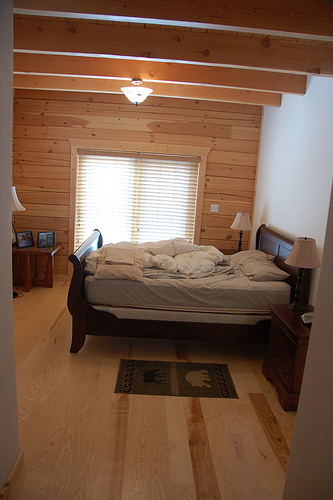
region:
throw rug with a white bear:
[117, 355, 244, 401]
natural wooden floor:
[144, 428, 233, 495]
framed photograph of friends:
[37, 229, 56, 247]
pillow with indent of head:
[241, 261, 288, 280]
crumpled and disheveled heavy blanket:
[102, 237, 223, 278]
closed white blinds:
[69, 142, 205, 250]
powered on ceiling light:
[121, 75, 154, 105]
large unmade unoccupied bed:
[56, 221, 310, 358]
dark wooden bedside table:
[247, 309, 317, 409]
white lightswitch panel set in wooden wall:
[207, 203, 219, 216]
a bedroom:
[15, 7, 315, 411]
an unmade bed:
[82, 226, 291, 306]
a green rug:
[113, 348, 237, 401]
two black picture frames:
[14, 224, 55, 244]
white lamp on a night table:
[222, 202, 250, 250]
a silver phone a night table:
[299, 306, 316, 328]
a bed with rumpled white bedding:
[101, 233, 223, 275]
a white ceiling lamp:
[117, 69, 159, 111]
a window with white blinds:
[65, 133, 210, 250]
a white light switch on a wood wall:
[209, 199, 224, 218]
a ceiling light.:
[116, 48, 162, 117]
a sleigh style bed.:
[63, 216, 312, 351]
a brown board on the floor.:
[185, 397, 220, 498]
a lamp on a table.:
[281, 235, 319, 308]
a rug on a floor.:
[104, 358, 236, 398]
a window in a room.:
[69, 141, 210, 252]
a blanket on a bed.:
[94, 228, 230, 293]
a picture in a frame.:
[32, 221, 60, 257]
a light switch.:
[206, 198, 225, 217]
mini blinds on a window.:
[71, 146, 209, 259]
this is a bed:
[90, 235, 275, 304]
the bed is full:
[90, 241, 273, 321]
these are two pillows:
[241, 246, 267, 275]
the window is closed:
[75, 159, 191, 219]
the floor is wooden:
[97, 424, 243, 497]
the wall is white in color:
[271, 146, 322, 201]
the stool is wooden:
[21, 252, 53, 285]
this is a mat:
[107, 359, 233, 397]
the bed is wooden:
[68, 249, 83, 271]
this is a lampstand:
[280, 237, 319, 305]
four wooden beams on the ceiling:
[229, 7, 330, 111]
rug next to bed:
[113, 357, 236, 420]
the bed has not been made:
[124, 222, 289, 293]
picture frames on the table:
[14, 226, 63, 250]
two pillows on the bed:
[232, 248, 280, 286]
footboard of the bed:
[60, 219, 109, 346]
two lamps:
[228, 208, 330, 269]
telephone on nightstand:
[287, 301, 313, 331]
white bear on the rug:
[183, 370, 223, 395]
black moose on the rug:
[136, 361, 170, 387]